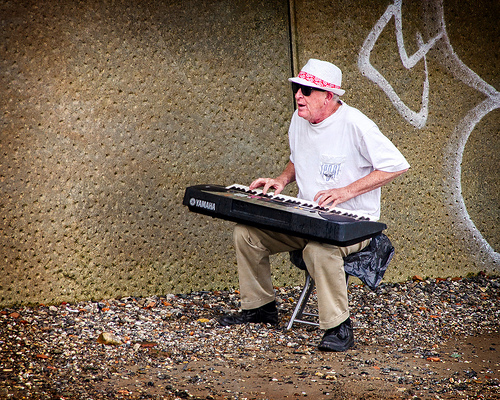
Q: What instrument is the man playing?
A: Keyboard.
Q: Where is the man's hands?
A: On the keys.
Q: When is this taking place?
A: Daytime.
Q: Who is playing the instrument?
A: A man.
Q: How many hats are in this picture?
A: One.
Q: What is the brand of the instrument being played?
A: Yamaha.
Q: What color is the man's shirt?
A: White.